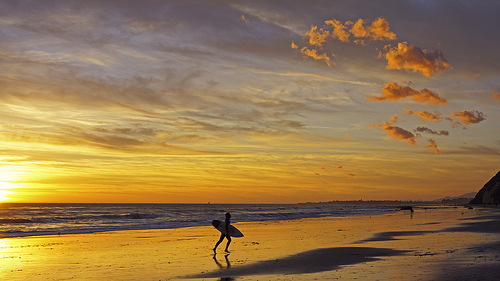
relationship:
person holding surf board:
[212, 209, 234, 256] [208, 216, 247, 239]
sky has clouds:
[0, 4, 499, 174] [290, 14, 494, 155]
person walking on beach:
[212, 209, 234, 256] [0, 212, 498, 276]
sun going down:
[0, 152, 39, 202] [2, 189, 471, 200]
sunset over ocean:
[0, 152, 39, 202] [3, 202, 203, 225]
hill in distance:
[468, 168, 499, 207] [426, 173, 499, 204]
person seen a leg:
[212, 209, 234, 256] [224, 237, 233, 255]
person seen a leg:
[212, 209, 234, 256] [210, 232, 225, 254]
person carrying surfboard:
[212, 209, 234, 256] [208, 216, 247, 239]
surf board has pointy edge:
[208, 216, 247, 239] [238, 228, 245, 239]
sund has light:
[0, 152, 39, 202] [0, 130, 210, 279]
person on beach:
[212, 209, 234, 256] [0, 205, 499, 281]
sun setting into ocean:
[0, 152, 39, 202] [3, 202, 203, 225]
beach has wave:
[0, 212, 498, 276] [0, 224, 91, 229]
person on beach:
[212, 209, 234, 256] [0, 212, 498, 276]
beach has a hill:
[0, 212, 498, 276] [468, 168, 499, 207]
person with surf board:
[212, 209, 234, 256] [208, 216, 247, 239]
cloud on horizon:
[152, 157, 400, 199] [3, 163, 476, 195]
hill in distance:
[457, 189, 479, 200] [426, 173, 499, 204]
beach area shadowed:
[0, 212, 498, 276] [255, 243, 390, 274]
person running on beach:
[212, 209, 234, 256] [0, 212, 498, 276]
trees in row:
[325, 197, 470, 204] [277, 194, 413, 214]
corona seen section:
[14, 163, 60, 201] [12, 169, 24, 181]